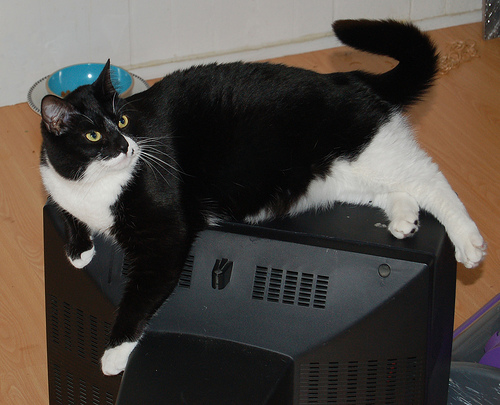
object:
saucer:
[21, 71, 59, 111]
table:
[461, 55, 488, 204]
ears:
[34, 59, 120, 132]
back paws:
[378, 199, 498, 269]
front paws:
[57, 238, 150, 376]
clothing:
[461, 295, 496, 383]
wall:
[134, 6, 277, 41]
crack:
[114, 11, 144, 57]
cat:
[31, 14, 491, 290]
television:
[33, 242, 465, 397]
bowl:
[46, 60, 139, 92]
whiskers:
[131, 131, 188, 177]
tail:
[325, 11, 443, 98]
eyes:
[76, 111, 134, 141]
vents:
[247, 259, 332, 311]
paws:
[378, 199, 498, 269]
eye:
[81, 126, 107, 142]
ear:
[93, 61, 137, 105]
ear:
[37, 91, 81, 136]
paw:
[55, 233, 112, 272]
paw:
[373, 194, 427, 246]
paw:
[93, 323, 141, 380]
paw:
[438, 210, 497, 277]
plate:
[24, 78, 157, 111]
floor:
[0, 85, 495, 311]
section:
[403, 15, 497, 121]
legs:
[325, 126, 498, 273]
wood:
[436, 97, 498, 164]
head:
[42, 81, 147, 170]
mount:
[205, 251, 238, 290]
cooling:
[247, 265, 314, 301]